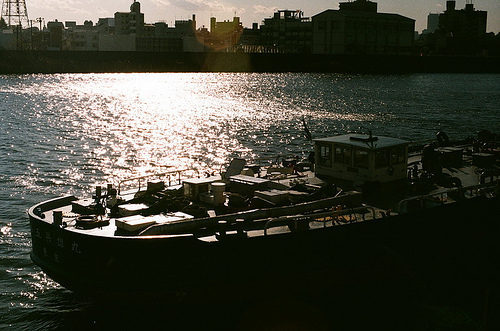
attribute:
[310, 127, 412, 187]
room — little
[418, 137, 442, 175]
person — barely visible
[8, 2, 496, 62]
buildings — multiple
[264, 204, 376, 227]
railing — metal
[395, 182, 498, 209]
railing — metal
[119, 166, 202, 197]
railing — metal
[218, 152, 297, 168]
railing — metal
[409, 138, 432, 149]
railing — metal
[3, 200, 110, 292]
writing — asian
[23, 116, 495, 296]
ship — large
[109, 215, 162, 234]
hatch — square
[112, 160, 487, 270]
boat — long, flat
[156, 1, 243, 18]
clouds — white